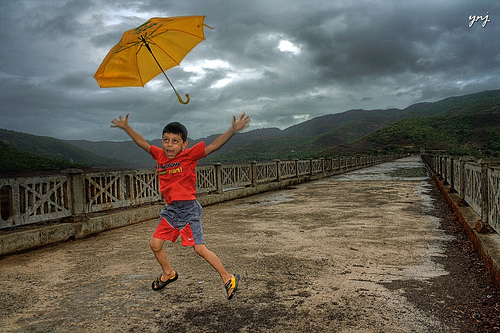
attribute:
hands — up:
[94, 96, 260, 171]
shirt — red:
[141, 140, 209, 200]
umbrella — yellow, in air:
[86, 6, 248, 138]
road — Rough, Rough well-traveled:
[1, 148, 496, 330]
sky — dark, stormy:
[208, 4, 465, 99]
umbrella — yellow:
[82, 12, 224, 107]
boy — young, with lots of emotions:
[103, 107, 265, 300]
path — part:
[314, 126, 456, 260]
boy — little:
[91, 130, 273, 245]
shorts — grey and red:
[149, 198, 206, 247]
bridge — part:
[27, 130, 444, 331]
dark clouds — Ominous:
[3, 0, 499, 138]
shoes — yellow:
[151, 266, 178, 291]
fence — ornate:
[424, 151, 499, 241]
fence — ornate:
[0, 148, 412, 225]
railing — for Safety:
[3, 149, 414, 238]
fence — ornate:
[0, 147, 417, 233]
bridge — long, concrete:
[257, 141, 428, 265]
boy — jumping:
[97, 107, 309, 324]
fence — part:
[17, 174, 82, 220]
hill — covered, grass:
[317, 88, 499, 146]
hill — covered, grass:
[221, 105, 401, 154]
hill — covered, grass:
[71, 124, 283, 168]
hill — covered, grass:
[0, 127, 137, 176]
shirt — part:
[169, 173, 184, 189]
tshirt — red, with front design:
[147, 142, 202, 196]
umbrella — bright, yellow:
[94, 13, 216, 103]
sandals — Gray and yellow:
[146, 269, 241, 297]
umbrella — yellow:
[79, 7, 226, 122]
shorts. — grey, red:
[142, 205, 209, 245]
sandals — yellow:
[148, 273, 234, 294]